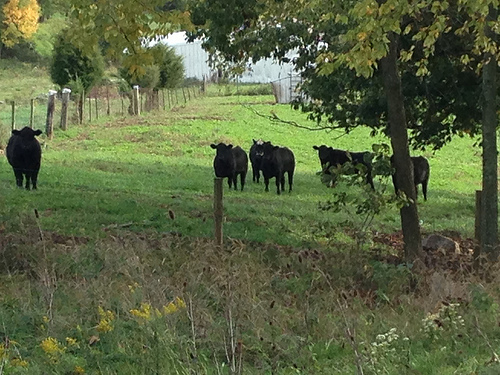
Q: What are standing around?
A: Cows.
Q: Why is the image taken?
A: Remembrance.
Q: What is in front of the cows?
A: Tree.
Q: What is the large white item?
A: Building.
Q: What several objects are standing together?
A: Cows.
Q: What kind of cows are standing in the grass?
A: Black.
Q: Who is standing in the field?
A: Cows.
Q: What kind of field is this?
A: Green grassy field.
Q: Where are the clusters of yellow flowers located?
A: In grass.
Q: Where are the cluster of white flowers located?
A: In grass.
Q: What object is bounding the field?
A: Fence.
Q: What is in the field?
A: Shaded area.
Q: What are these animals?
A: They are cows.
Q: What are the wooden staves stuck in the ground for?
A: They are part of a fence that has gone to disrepair.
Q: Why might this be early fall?
A: Because some trees have colored leaves.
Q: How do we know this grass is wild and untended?
A: Because it is patchy, uneven and weedy.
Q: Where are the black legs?
A: On the cows.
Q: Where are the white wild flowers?
A: Near the right, lower corner, amidst the tall grass.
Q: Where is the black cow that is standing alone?
A: To the far left, nearest the fence.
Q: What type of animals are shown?
A: Cows.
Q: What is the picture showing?
A: Cows in a field.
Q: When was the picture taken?
A: During the day.